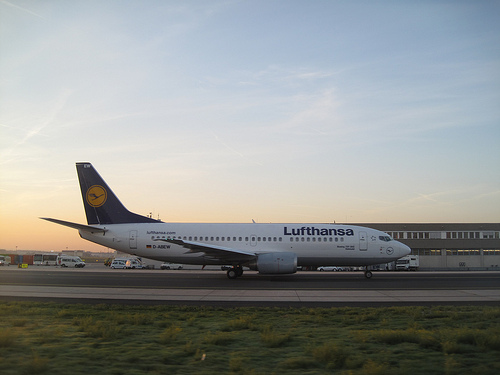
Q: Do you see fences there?
A: No, there are no fences.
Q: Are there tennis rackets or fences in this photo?
A: No, there are no fences or tennis rackets.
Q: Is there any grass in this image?
A: Yes, there is grass.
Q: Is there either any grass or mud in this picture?
A: Yes, there is grass.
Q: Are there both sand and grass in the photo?
A: No, there is grass but no sand.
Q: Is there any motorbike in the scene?
A: No, there are no motorcycles.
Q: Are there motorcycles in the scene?
A: No, there are no motorcycles.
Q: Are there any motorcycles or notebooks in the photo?
A: No, there are no motorcycles or notebooks.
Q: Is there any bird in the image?
A: No, there are no birds.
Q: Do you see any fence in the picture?
A: No, there are no fences.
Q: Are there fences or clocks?
A: No, there are no fences or clocks.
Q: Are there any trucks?
A: Yes, there is a truck.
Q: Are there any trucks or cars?
A: Yes, there is a truck.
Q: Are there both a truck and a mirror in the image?
A: No, there is a truck but no mirrors.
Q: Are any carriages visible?
A: No, there are no carriages.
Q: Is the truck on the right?
A: Yes, the truck is on the right of the image.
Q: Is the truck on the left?
A: No, the truck is on the right of the image.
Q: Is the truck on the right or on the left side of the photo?
A: The truck is on the right of the image.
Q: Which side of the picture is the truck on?
A: The truck is on the right of the image.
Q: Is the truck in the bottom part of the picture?
A: Yes, the truck is in the bottom of the image.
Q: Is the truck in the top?
A: No, the truck is in the bottom of the image.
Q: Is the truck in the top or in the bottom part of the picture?
A: The truck is in the bottom of the image.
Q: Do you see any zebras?
A: No, there are no zebras.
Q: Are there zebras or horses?
A: No, there are no zebras or horses.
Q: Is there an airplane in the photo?
A: Yes, there is an airplane.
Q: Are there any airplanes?
A: Yes, there is an airplane.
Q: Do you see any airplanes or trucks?
A: Yes, there is an airplane.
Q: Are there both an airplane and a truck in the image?
A: Yes, there are both an airplane and a truck.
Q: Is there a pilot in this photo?
A: No, there are no pilots.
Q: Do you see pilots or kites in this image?
A: No, there are no pilots or kites.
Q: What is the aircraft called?
A: The aircraft is an airplane.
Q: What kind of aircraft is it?
A: The aircraft is an airplane.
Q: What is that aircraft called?
A: This is an airplane.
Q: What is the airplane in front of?
A: The airplane is in front of the building.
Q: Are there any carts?
A: No, there are no carts.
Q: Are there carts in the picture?
A: No, there are no carts.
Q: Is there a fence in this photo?
A: No, there are no fences.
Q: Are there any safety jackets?
A: No, there are no safety jackets.